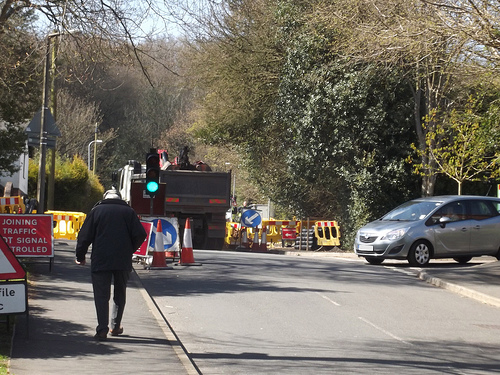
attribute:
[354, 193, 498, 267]
car — silver 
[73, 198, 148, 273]
jacket — black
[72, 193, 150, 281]
jacket — black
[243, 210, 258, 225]
arrow — white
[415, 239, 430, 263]
tire — black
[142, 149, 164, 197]
light — traffic light, green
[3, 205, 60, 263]
sign — white, red